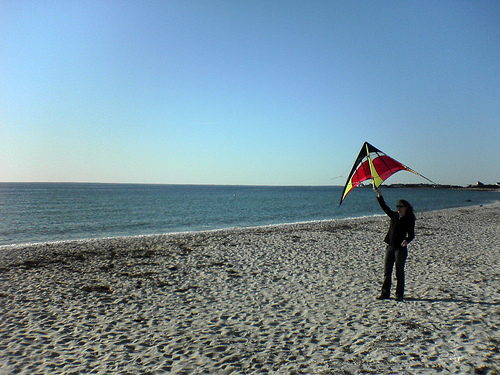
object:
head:
[391, 198, 414, 212]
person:
[372, 189, 415, 301]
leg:
[378, 247, 394, 293]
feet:
[371, 294, 393, 302]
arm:
[375, 194, 396, 216]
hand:
[372, 185, 379, 195]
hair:
[396, 200, 420, 221]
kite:
[326, 140, 436, 205]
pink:
[377, 161, 391, 169]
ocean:
[0, 183, 499, 262]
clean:
[0, 181, 499, 244]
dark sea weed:
[23, 243, 158, 274]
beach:
[0, 199, 499, 374]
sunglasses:
[394, 206, 408, 212]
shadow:
[386, 296, 499, 306]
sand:
[0, 201, 499, 374]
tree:
[434, 182, 459, 188]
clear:
[0, 0, 499, 187]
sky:
[0, 0, 499, 187]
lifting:
[362, 174, 395, 216]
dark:
[385, 222, 408, 240]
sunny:
[110, 43, 247, 160]